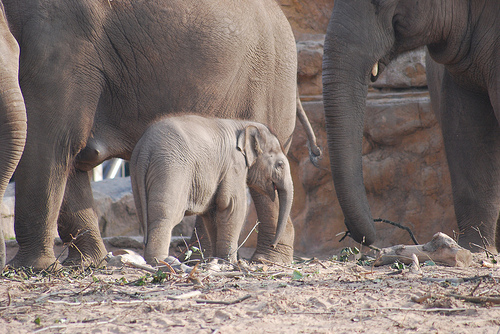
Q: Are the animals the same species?
A: Yes, all the animals are elephants.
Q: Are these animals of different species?
A: No, all the animals are elephants.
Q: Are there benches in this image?
A: No, there are no benches.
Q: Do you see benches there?
A: No, there are no benches.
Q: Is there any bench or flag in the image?
A: No, there are no benches or flags.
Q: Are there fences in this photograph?
A: No, there are no fences.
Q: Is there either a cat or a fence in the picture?
A: No, there are no fences or cats.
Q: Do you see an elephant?
A: Yes, there is an elephant.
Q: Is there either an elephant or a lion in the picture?
A: Yes, there is an elephant.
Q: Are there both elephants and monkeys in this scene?
A: No, there is an elephant but no monkeys.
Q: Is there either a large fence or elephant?
A: Yes, there is a large elephant.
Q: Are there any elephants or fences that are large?
A: Yes, the elephant is large.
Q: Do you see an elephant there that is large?
A: Yes, there is a large elephant.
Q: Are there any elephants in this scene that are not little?
A: Yes, there is a large elephant.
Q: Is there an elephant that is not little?
A: Yes, there is a large elephant.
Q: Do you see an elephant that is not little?
A: Yes, there is a large elephant.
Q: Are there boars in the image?
A: No, there are no boars.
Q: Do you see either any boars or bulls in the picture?
A: No, there are no boars or bulls.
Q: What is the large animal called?
A: The animal is an elephant.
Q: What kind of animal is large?
A: The animal is an elephant.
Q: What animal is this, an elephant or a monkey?
A: This is an elephant.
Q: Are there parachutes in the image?
A: No, there are no parachutes.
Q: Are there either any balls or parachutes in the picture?
A: No, there are no parachutes or balls.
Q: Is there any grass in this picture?
A: Yes, there is grass.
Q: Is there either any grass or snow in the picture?
A: Yes, there is grass.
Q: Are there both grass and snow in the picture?
A: No, there is grass but no snow.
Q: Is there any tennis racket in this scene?
A: No, there are no rackets.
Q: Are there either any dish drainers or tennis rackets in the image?
A: No, there are no tennis rackets or dish drainers.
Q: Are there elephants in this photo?
A: Yes, there is an elephant.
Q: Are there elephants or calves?
A: Yes, there is an elephant.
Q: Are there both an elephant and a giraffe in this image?
A: No, there is an elephant but no giraffes.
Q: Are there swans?
A: No, there are no swans.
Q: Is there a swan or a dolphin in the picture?
A: No, there are no swans or dolphins.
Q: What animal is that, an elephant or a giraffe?
A: That is an elephant.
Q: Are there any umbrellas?
A: No, there are no umbrellas.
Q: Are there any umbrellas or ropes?
A: No, there are no umbrellas or ropes.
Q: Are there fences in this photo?
A: No, there are no fences.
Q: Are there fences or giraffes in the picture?
A: No, there are no fences or giraffes.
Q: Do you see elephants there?
A: Yes, there is an elephant.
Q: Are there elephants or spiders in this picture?
A: Yes, there is an elephant.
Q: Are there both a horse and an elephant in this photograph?
A: No, there is an elephant but no horses.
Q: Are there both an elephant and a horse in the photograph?
A: No, there is an elephant but no horses.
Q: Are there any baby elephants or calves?
A: Yes, there is a baby elephant.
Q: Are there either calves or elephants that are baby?
A: Yes, the elephant is a baby.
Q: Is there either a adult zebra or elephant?
A: Yes, there is an adult elephant.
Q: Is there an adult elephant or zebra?
A: Yes, there is an adult elephant.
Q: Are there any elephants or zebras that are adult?
A: Yes, the elephant is adult.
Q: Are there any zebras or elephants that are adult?
A: Yes, the elephant is adult.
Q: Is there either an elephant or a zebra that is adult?
A: Yes, the elephant is adult.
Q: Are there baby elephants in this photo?
A: Yes, there is a baby elephant.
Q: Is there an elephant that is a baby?
A: Yes, there is an elephant that is a baby.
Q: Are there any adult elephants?
A: Yes, there is an adult elephant.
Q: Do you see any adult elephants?
A: Yes, there is an adult elephant.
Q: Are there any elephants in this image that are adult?
A: Yes, there is an elephant that is adult.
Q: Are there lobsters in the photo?
A: No, there are no lobsters.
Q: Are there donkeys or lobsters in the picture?
A: No, there are no lobsters or donkeys.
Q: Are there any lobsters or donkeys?
A: No, there are no lobsters or donkeys.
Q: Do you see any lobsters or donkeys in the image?
A: No, there are no lobsters or donkeys.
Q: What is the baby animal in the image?
A: The animal is an elephant.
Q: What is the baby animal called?
A: The animal is an elephant.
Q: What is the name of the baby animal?
A: The animal is an elephant.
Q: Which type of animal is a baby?
A: The animal is an elephant.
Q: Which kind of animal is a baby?
A: The animal is an elephant.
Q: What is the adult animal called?
A: The animal is an elephant.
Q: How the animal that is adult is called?
A: The animal is an elephant.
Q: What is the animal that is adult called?
A: The animal is an elephant.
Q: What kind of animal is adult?
A: The animal is an elephant.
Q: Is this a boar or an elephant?
A: This is an elephant.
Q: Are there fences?
A: No, there are no fences.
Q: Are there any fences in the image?
A: No, there are no fences.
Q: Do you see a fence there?
A: No, there are no fences.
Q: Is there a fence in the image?
A: No, there are no fences.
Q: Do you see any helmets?
A: No, there are no helmets.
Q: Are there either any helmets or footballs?
A: No, there are no helmets or footballs.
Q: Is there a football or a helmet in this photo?
A: No, there are no helmets or footballs.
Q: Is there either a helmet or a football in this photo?
A: No, there are no helmets or footballs.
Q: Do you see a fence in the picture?
A: No, there are no fences.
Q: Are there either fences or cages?
A: No, there are no fences or cages.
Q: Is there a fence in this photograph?
A: No, there are no fences.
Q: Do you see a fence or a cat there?
A: No, there are no fences or cats.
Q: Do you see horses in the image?
A: No, there are no horses.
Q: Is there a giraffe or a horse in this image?
A: No, there are no horses or giraffes.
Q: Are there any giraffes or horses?
A: No, there are no horses or giraffes.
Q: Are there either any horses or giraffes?
A: No, there are no horses or giraffes.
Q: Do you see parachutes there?
A: No, there are no parachutes.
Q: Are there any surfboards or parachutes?
A: No, there are no parachutes or surfboards.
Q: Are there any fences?
A: No, there are no fences.